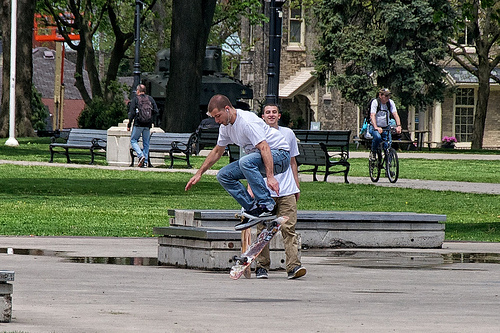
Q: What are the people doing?
A: Skating.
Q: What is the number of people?
A: Four.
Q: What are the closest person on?
A: Skateboard.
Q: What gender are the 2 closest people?
A: Male.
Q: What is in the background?
A: Buildings.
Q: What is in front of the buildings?
A: Trees.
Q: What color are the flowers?
A: Purple.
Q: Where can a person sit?
A: Benches.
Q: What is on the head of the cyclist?
A: Cap.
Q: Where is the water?
A: Pavement behind the skateboarders.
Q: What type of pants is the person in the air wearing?
A: Jeans.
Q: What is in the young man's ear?
A: Earphone.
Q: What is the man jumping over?
A: Skateboard.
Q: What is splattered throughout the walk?
A: Water puddles.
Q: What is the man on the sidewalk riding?
A: Bicycle.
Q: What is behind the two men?
A: Bench.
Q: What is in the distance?
A: Building.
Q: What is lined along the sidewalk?
A: Benches.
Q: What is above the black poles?
A: Lights.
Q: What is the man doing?
A: A trick on the skateboard.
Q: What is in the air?
A: The skateboarder.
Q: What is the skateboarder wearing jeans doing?
A: The trick.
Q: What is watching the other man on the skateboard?
A: The man.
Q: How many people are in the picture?
A: Four.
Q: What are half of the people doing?
A: Skateboarding.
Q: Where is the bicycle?
A: Right.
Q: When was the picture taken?
A: Daytime.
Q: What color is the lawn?
A: Green.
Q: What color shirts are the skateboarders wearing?
A: White.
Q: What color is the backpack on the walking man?
A: Brown.